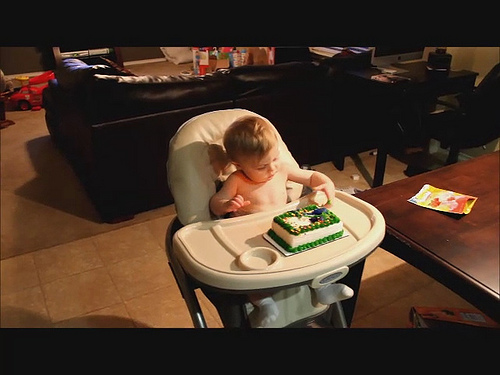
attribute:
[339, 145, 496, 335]
table — brown, wooden, dinner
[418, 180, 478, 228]
paper — yellow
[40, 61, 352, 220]
sofa — black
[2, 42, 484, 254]
couch — long, black, leather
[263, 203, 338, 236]
green cake — small, white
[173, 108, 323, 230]
boy — brown haired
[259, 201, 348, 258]
cake — white, green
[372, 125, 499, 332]
table — wooden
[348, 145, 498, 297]
table — wooden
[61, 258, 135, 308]
floor — tile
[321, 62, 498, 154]
table — small, black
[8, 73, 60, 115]
riding toy — plastic, child's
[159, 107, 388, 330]
highchair — white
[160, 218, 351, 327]
frame — still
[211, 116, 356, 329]
toddler — blonde